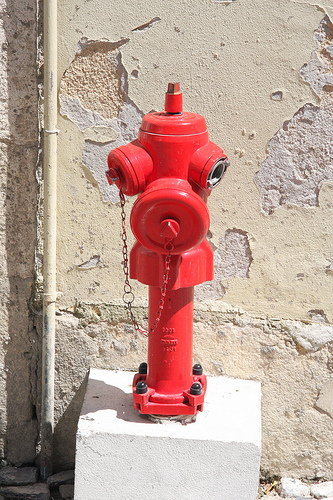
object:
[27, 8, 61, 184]
pole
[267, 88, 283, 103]
wall damage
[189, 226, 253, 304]
chip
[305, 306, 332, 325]
chip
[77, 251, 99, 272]
chip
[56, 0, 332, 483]
wall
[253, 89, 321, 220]
wall cracks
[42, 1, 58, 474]
conduit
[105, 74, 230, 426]
hydrant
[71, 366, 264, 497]
concrete block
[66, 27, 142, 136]
crack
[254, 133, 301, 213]
paint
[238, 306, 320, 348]
cracks